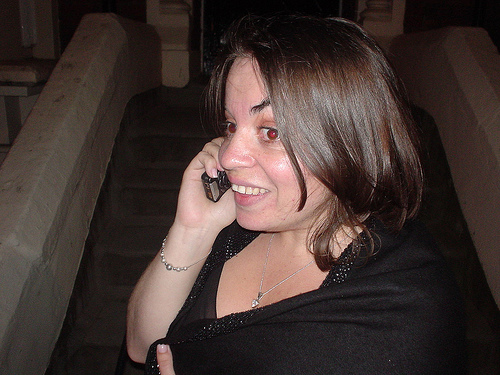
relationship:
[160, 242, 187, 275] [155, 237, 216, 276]
charms are on bracelet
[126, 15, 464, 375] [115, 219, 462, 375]
woman wearing a sweater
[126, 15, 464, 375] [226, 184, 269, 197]
woman has teeth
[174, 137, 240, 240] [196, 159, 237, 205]
hand holding cell phone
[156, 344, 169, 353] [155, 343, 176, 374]
fingernail on thumb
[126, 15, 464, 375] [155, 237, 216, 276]
woman wearing a bracelet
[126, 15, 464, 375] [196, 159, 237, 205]
woman holding cell phone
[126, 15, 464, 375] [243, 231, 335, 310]
woman wearing a necklace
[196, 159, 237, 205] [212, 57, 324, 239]
cell phone on side of face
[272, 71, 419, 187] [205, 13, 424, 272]
light reflected in hair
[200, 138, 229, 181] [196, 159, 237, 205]
fingers are on cell phone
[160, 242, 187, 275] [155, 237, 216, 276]
charms around bracelet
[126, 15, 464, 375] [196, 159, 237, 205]
woman talking on her cell phone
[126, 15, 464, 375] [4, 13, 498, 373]
woman standing on a staircase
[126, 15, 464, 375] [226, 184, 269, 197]
woman showing her teeth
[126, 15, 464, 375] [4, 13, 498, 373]
woman standing on staircase